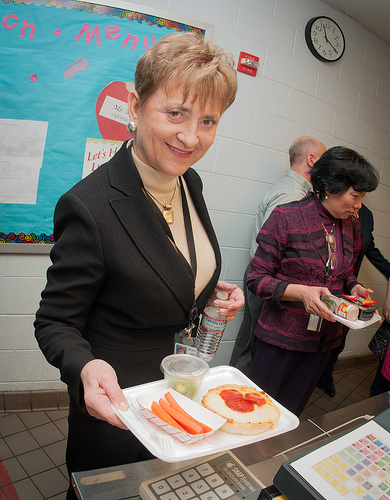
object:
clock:
[303, 14, 346, 65]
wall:
[0, 43, 389, 351]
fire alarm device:
[232, 55, 264, 82]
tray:
[108, 363, 303, 465]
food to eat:
[133, 352, 281, 447]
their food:
[316, 293, 385, 332]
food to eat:
[319, 291, 379, 329]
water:
[190, 285, 230, 364]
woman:
[33, 30, 247, 498]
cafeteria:
[0, 1, 389, 500]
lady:
[242, 143, 381, 420]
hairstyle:
[133, 33, 239, 116]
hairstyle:
[307, 146, 379, 204]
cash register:
[135, 419, 390, 499]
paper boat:
[134, 385, 230, 446]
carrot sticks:
[149, 392, 212, 436]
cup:
[158, 352, 211, 400]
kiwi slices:
[166, 371, 201, 401]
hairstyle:
[285, 137, 320, 170]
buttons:
[309, 433, 388, 500]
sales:
[108, 289, 301, 465]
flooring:
[0, 363, 384, 498]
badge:
[173, 341, 198, 358]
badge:
[305, 313, 324, 335]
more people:
[228, 135, 390, 412]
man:
[231, 128, 332, 378]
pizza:
[199, 383, 282, 436]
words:
[0, 14, 159, 178]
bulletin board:
[0, 0, 205, 255]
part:
[5, 419, 54, 466]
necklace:
[141, 182, 178, 229]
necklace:
[318, 219, 339, 276]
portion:
[284, 77, 366, 123]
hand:
[210, 280, 246, 323]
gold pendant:
[162, 203, 175, 225]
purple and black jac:
[242, 193, 364, 356]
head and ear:
[287, 135, 327, 184]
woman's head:
[124, 29, 237, 181]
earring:
[124, 119, 138, 135]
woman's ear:
[126, 89, 141, 135]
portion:
[334, 164, 352, 178]